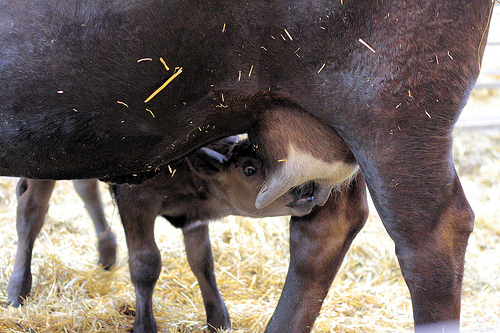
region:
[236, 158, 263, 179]
An eye of a baby cow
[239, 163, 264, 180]
An eye of a calf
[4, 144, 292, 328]
A brown baby cow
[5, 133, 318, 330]
A brown baby calf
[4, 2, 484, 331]
A baby calf under the mother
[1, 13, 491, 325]
A infant cow under the mother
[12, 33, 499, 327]
A baby cow nursing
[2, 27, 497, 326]
A baby calf nursing from the mother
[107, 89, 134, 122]
A piece of straw on a cow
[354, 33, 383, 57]
A piece of straw on a cow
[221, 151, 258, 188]
This calf has a very deep black eyes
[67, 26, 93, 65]
The belly of this cow is a very dark brown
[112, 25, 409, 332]
Jackson Mingus is responsible for this photo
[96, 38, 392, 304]
There is a wide variety of hay and straw in the photo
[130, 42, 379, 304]
This was a photo that was published in National Geographic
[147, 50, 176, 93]
There is a piece of straw on this cow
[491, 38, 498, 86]
There is a steel fence that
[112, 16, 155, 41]
This particular patch of cow is very, very brown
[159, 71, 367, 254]
a calf next to udders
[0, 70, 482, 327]
a calf below his mom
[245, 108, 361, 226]
the udders of cow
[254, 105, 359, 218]
udders are brown and white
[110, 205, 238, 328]
front legs of calf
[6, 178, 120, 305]
back legs of calf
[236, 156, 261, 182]
big eye of cow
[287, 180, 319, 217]
teeth of calf can be seen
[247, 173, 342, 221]
teats of udders are gray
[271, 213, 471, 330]
back feet of cow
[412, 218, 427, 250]
edge of a leg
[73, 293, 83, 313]
part of the grass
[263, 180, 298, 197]
part of a milk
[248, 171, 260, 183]
eye of a dog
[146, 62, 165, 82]
body of a cow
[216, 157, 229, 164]
ear of a cow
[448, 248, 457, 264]
side of a leg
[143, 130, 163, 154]
back of a cow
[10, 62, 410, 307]
calf face by mother's teats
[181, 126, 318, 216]
surprised expression of calf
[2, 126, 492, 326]
yellow hay under cow and calf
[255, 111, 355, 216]
brown and tan udder covered in hair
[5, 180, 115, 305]
rear calf legs spread apart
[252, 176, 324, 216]
dark nose and lightly open mouth between teats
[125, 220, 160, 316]
bulging around foreleg joint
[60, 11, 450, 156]
bits of straw on side of fur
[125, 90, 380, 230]
curve formed by thigh and underbelly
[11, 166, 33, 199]
dark oval opening on rear of leg